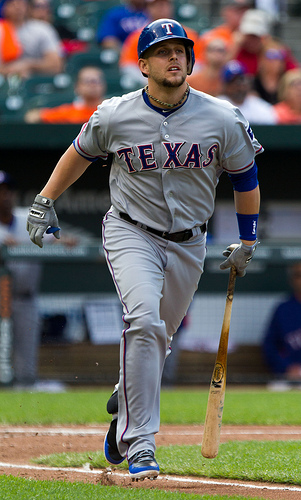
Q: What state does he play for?
A: Texas.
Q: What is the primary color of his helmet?
A: Blue.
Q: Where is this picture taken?
A: Baseball game.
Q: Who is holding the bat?
A: Player.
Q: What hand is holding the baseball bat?
A: Left.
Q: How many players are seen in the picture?
A: One.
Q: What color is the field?
A: Green.